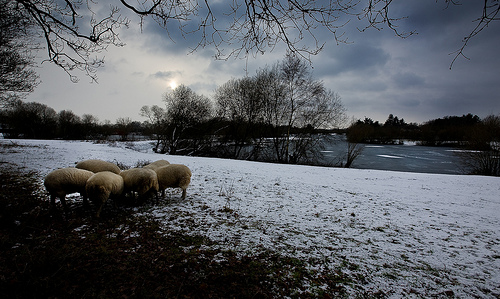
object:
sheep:
[44, 167, 110, 210]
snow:
[3, 140, 499, 297]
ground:
[1, 139, 500, 298]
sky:
[0, 0, 497, 115]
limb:
[112, 1, 176, 27]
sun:
[168, 79, 179, 90]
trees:
[216, 48, 348, 164]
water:
[118, 136, 500, 174]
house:
[100, 125, 125, 142]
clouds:
[108, 55, 264, 87]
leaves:
[1, 211, 303, 298]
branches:
[12, 2, 131, 84]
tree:
[1, 2, 44, 153]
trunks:
[163, 139, 311, 163]